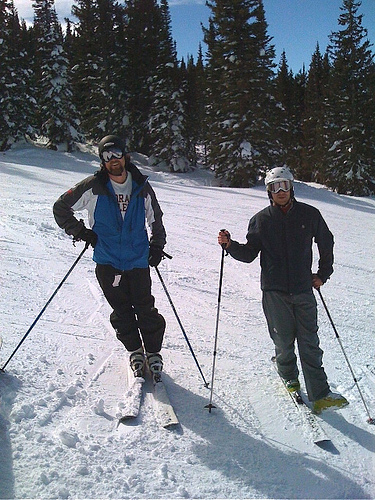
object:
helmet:
[265, 167, 294, 186]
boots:
[313, 390, 349, 414]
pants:
[94, 261, 166, 353]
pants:
[261, 289, 331, 402]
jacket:
[52, 162, 166, 272]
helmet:
[99, 134, 125, 158]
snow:
[171, 122, 180, 132]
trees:
[322, 0, 375, 197]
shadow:
[145, 372, 363, 500]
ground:
[0, 139, 374, 500]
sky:
[275, 1, 320, 42]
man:
[217, 166, 348, 415]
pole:
[204, 247, 224, 412]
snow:
[0, 147, 375, 500]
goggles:
[266, 181, 291, 194]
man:
[51, 135, 172, 380]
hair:
[124, 154, 130, 168]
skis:
[270, 355, 333, 445]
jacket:
[224, 199, 334, 297]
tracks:
[39, 342, 116, 432]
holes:
[281, 171, 284, 174]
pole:
[1, 245, 87, 370]